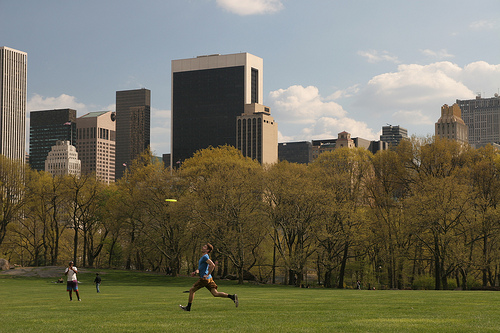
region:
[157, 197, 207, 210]
yellow small flying frisbee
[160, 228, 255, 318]
young man running in park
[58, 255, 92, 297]
black man taking pictures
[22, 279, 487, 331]
large green park area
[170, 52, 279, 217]
tall black and white building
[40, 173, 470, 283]
large tree wooded area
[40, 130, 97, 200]
point gray building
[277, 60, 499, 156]
fluffy white clouds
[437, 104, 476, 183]
brown small pointy building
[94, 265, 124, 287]
small child playing at park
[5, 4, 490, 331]
people at the park in a city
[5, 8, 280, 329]
park landscape within a city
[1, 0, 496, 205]
city landscape during the day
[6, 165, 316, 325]
person playing frisbee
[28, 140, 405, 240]
frisbee flying at tree level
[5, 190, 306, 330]
people at the park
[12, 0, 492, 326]
park area within downtown region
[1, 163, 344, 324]
sports ion the park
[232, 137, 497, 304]
trees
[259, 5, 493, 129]
blue sky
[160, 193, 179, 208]
yellow frisbee in the air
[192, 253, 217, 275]
blue tee shirt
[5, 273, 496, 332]
green grass in a city park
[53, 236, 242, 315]
three people in a city park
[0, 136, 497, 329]
a park in the city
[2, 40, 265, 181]
city sky scrapers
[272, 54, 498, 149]
white clouds in a blue sky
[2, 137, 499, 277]
row of green trees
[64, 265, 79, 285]
a white short sleeve shirt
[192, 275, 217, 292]
tan shorts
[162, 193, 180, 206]
The yellow flying disc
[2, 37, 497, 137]
Skyline of the City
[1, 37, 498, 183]
Buildings shown in the background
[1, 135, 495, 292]
Trees at the end of the park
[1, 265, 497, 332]
Grass field in the park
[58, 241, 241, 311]
People shown in the park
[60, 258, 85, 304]
Person in white t-shirt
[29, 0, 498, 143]
Clouds in the sky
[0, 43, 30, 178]
The tallest building shown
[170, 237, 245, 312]
Man in the blue t-shirt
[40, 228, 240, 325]
Two men playing frisbee.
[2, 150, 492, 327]
A park.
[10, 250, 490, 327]
A large open field.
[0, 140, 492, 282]
A row of trees.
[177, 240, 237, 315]
The man is wearing a blue t-shirt.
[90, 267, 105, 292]
A person, in the distance, wearing a dark colored jacket.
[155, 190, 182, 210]
A yellow frisbee.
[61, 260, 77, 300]
The man is wearing a white t-shirt.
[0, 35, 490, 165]
Skyscrapers tower above the tree line, in the distance.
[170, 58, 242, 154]
The windows on the building appear black.